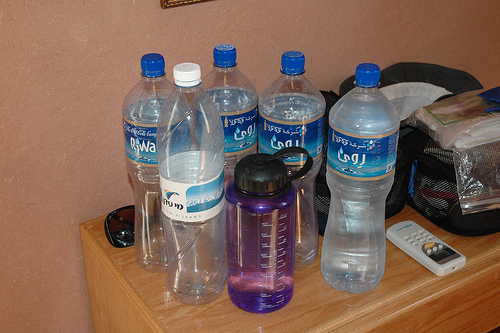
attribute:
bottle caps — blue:
[207, 40, 396, 91]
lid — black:
[230, 150, 290, 194]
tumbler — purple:
[218, 187, 305, 316]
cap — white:
[167, 64, 206, 83]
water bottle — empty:
[156, 69, 239, 312]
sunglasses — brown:
[101, 200, 148, 262]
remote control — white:
[390, 213, 462, 291]